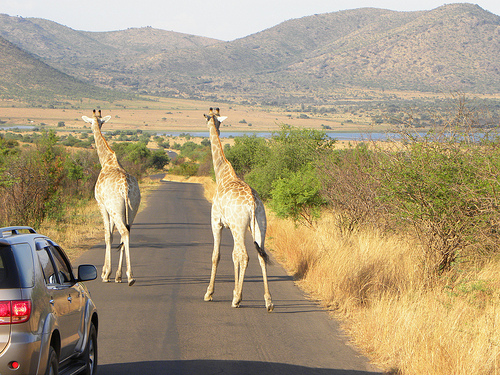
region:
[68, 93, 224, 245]
2 giraffes walking on street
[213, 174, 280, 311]
giraffe with light colored coat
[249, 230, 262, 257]
giraffe with small tuft on tail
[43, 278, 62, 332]
gray vehicle behind giraffes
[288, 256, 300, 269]
shadow of first giraffe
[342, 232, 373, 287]
dry brittle grass by road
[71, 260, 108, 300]
side mirror of vehicle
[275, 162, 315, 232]
small green bush in grass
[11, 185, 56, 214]
bare tree by street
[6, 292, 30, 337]
red brake light on vehicle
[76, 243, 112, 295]
side mirror on right side of car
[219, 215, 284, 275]
black fur on end of tail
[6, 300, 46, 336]
rear right brake light on car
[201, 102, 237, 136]
back of head on giraffee on right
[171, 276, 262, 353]
grey asphalt road in middle of photo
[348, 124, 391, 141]
blue area filled with water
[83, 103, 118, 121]
horns on left side of giraffee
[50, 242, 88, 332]
right doors on car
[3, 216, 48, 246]
luggage rack on top of car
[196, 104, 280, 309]
giraffe on the road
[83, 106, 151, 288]
giraffe walking on road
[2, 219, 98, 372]
sports utility vehicle on road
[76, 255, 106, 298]
passenger side rearview mirror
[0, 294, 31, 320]
passenger side brake light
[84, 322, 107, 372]
front passenger side tire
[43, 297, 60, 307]
door handle on truck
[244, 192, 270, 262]
tail on the giraffe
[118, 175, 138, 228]
tail on the farthest giraffe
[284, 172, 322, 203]
green leaves on the bush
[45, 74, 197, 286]
this is a girrafe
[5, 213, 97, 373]
this is a car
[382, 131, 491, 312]
this is a tree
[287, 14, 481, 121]
this is a mountain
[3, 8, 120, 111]
this is a mountain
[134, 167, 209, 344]
this is a road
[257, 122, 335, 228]
this is a tree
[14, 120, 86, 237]
this is a tree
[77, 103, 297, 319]
Two giraffes on a street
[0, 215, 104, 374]
A car approaching two giraffes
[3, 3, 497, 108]
Large hills in the background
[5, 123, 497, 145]
River flowing in the background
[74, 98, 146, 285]
Giraffe takes another step down the road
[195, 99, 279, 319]
Giraffe lands his next step on the street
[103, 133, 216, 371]
Portion of long, winding road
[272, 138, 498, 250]
Healthy trees to the right of the giraffes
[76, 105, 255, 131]
Heads of the two giraffes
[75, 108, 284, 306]
Two giraffes in the road.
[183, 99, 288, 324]
A giraffe standing in road.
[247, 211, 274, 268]
The giraffe has long black tail.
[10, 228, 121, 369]
A gray car behind the giraffes.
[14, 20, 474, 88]
Mountains and hills in the background.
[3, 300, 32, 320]
Red brake lights on the car.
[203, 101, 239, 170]
The giraffe has a long neck.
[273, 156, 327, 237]
The tree is green.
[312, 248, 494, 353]
The grass is tall and brown.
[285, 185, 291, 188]
A green leaf on a plant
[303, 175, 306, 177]
A green leaf on a plant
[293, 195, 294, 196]
A green leaf on a plant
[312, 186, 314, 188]
A green leaf on a plant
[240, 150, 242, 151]
A green leaf on a plant